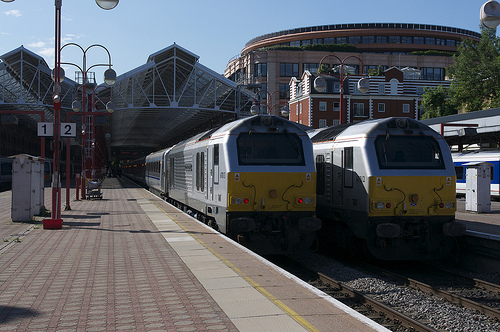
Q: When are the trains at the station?
A: Day time.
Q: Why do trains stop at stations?
A: To take on passengers.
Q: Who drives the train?
A: Conductor.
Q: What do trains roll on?
A: Rails.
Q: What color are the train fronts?
A: Yellow.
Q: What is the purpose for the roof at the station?
A: To keep off weather.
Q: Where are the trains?
A: Station.